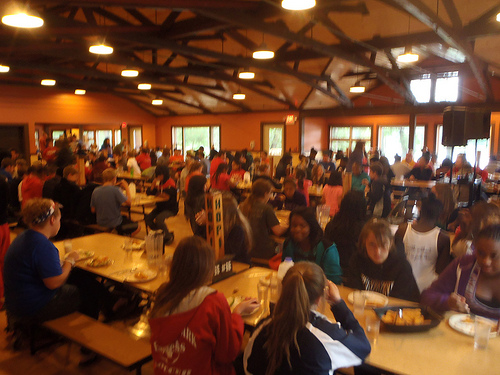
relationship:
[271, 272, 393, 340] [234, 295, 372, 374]
girl wearing jacket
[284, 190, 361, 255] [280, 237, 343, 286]
girl wearing jacket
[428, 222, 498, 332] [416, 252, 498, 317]
girl wearing jacket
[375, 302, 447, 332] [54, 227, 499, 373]
lunch on table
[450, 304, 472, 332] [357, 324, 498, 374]
cup on table top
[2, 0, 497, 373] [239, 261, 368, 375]
cafeteria filled with girl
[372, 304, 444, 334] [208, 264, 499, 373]
bowl on table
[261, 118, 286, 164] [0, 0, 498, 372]
door to room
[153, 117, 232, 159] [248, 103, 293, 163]
window near door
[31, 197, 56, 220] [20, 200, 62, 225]
fabric in hair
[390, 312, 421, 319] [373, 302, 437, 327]
food in bowl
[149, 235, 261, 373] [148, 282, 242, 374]
girl wearing hoodie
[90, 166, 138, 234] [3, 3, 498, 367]
boy eating in a caffiteria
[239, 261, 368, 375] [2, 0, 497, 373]
girl eating in a cafeteria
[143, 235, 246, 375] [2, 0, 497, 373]
girl eating in a cafeteria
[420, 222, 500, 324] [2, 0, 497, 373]
girl eating in a cafeteria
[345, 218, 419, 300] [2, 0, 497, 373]
girl eating in a cafeteria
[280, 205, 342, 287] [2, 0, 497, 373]
girl eating in a cafeteria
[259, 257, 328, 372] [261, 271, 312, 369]
hair has ponytail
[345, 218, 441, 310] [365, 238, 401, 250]
girl wearing glasses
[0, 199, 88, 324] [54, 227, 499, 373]
girl sitting at table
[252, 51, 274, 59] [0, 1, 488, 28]
light hanging from ceiling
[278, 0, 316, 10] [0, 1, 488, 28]
light hanging from ceiling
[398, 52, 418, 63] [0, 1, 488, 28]
light hanging from ceiling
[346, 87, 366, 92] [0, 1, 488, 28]
light hanging from ceiling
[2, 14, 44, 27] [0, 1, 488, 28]
light hanging from ceiling